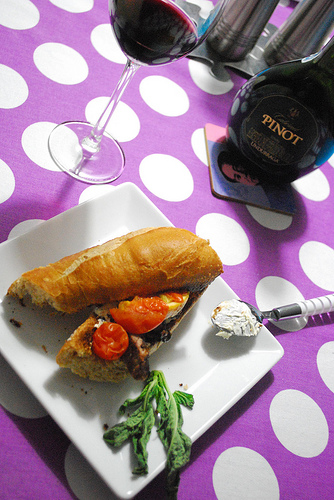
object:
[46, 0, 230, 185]
wine glass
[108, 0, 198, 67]
wine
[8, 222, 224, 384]
sandwich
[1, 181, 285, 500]
plate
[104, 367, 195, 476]
garnish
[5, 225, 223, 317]
loaf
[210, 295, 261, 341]
condiment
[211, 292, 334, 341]
spoon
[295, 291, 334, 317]
handle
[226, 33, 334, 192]
wine bottle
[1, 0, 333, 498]
table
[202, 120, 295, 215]
coaster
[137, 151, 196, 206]
dot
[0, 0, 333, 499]
tablecloth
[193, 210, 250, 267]
dot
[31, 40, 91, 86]
dot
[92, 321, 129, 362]
tomato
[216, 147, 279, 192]
chinese leader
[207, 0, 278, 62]
containers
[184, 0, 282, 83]
tray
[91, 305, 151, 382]
meats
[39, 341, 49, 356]
crumbs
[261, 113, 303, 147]
pinot